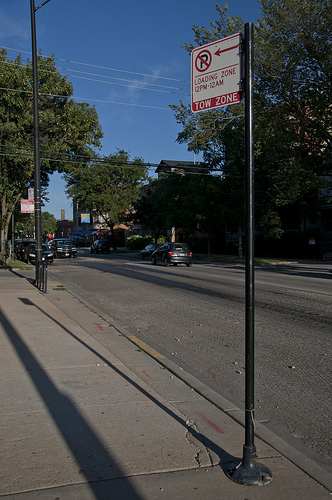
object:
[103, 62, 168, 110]
cloud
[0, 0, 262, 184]
sky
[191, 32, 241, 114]
sign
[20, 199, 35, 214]
sign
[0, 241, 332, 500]
ground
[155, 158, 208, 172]
roof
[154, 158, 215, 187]
building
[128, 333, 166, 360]
yellow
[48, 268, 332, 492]
curb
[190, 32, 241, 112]
red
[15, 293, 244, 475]
shadows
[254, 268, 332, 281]
shadows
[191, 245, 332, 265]
sidewalk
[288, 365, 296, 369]
stone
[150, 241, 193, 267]
car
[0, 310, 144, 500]
shadow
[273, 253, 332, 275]
curb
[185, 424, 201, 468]
cracks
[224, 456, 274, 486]
base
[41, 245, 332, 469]
road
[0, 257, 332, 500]
sidewalk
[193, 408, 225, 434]
paint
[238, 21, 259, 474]
pole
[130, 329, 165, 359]
writing